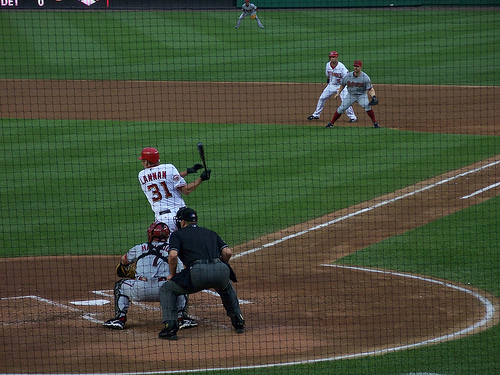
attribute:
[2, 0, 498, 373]
net — large 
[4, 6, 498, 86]
grass — green 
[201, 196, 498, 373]
grass — green 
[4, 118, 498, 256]
grass — green 